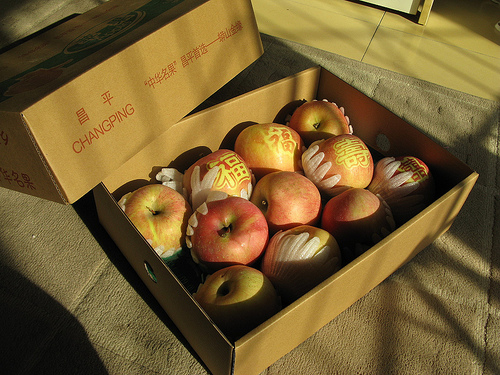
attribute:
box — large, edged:
[93, 64, 479, 375]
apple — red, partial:
[192, 196, 268, 268]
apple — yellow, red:
[198, 265, 280, 338]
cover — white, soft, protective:
[263, 227, 341, 299]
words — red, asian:
[72, 21, 244, 153]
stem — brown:
[221, 225, 232, 239]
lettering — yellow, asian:
[207, 151, 252, 190]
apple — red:
[182, 149, 253, 200]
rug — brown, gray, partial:
[1, 1, 500, 375]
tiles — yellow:
[250, 1, 500, 106]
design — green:
[0, 1, 181, 102]